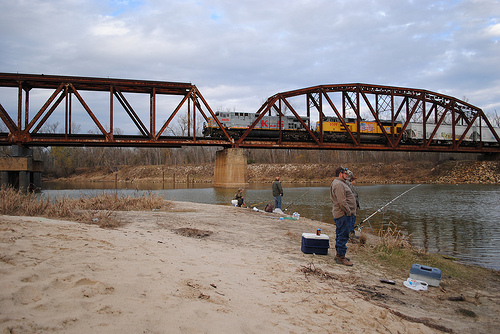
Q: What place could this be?
A: It is a lake.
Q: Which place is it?
A: It is a lake.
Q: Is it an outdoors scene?
A: Yes, it is outdoors.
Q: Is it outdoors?
A: Yes, it is outdoors.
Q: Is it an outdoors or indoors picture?
A: It is outdoors.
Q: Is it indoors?
A: No, it is outdoors.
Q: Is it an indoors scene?
A: No, it is outdoors.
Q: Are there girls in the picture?
A: No, there are no girls.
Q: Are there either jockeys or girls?
A: No, there are no girls or jockeys.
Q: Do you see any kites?
A: No, there are no kites.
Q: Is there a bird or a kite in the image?
A: No, there are no kites or birds.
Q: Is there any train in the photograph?
A: Yes, there is a train.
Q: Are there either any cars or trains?
A: Yes, there is a train.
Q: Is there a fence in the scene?
A: No, there are no fences.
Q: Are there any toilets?
A: No, there are no toilets.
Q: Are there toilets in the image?
A: No, there are no toilets.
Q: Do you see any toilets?
A: No, there are no toilets.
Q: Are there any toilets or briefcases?
A: No, there are no toilets or briefcases.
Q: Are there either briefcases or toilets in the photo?
A: No, there are no toilets or briefcases.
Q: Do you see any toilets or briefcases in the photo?
A: No, there are no toilets or briefcases.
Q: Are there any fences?
A: No, there are no fences.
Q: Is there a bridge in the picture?
A: Yes, there is a bridge.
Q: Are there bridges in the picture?
A: Yes, there is a bridge.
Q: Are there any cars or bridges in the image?
A: Yes, there is a bridge.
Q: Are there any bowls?
A: No, there are no bowls.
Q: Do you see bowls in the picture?
A: No, there are no bowls.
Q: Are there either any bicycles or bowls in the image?
A: No, there are no bowls or bicycles.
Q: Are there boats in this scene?
A: No, there are no boats.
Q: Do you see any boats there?
A: No, there are no boats.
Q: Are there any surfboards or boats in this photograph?
A: No, there are no boats or surfboards.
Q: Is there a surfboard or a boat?
A: No, there are no boats or surfboards.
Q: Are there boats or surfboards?
A: No, there are no boats or surfboards.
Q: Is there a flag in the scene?
A: No, there are no flags.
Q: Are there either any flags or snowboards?
A: No, there are no flags or snowboards.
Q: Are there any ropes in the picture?
A: No, there are no ropes.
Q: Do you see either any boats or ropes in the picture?
A: No, there are no ropes or boats.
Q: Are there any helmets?
A: No, there are no helmets.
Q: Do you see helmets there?
A: No, there are no helmets.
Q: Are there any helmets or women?
A: No, there are no helmets or women.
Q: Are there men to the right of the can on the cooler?
A: Yes, there is a man to the right of the can.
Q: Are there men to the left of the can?
A: No, the man is to the right of the can.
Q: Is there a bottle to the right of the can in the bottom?
A: No, there is a man to the right of the can.